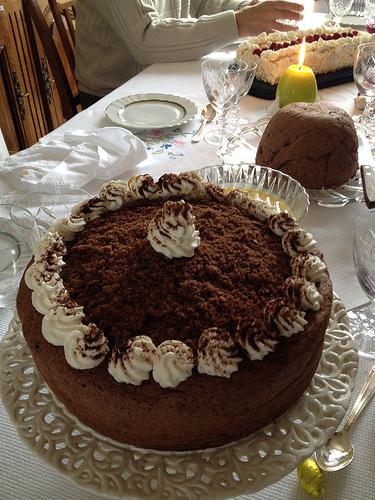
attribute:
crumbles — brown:
[46, 175, 298, 371]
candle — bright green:
[275, 61, 317, 109]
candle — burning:
[280, 65, 314, 110]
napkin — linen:
[8, 124, 148, 200]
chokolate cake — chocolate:
[15, 172, 332, 452]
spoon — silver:
[319, 361, 373, 485]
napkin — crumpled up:
[0, 124, 149, 195]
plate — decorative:
[3, 169, 365, 495]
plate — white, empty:
[105, 92, 199, 127]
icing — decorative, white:
[21, 173, 328, 384]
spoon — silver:
[313, 337, 358, 472]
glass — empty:
[190, 35, 256, 142]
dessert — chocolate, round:
[10, 168, 351, 449]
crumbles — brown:
[154, 283, 188, 311]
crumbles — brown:
[63, 198, 289, 342]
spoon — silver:
[190, 102, 215, 142]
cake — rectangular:
[233, 13, 373, 114]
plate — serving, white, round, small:
[97, 84, 205, 135]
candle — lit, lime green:
[291, 61, 329, 104]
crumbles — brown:
[86, 320, 135, 367]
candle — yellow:
[277, 60, 322, 108]